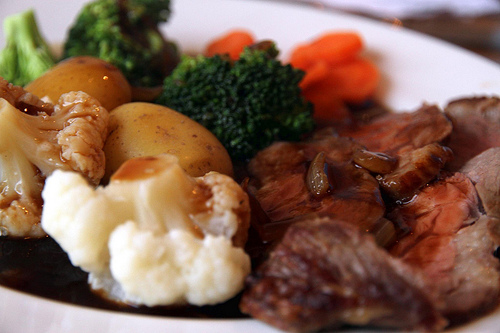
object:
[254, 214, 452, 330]
beef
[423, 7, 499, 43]
table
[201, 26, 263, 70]
carrots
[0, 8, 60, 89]
broccoli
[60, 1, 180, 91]
broccoli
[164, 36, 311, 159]
broccoli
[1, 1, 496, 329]
plate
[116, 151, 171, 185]
mushroom gravy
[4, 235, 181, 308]
sauce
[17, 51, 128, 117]
potato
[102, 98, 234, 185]
potato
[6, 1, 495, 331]
food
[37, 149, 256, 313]
cauliflower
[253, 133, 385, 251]
meat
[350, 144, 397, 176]
mushroom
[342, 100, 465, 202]
steak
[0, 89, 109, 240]
cauliflower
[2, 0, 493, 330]
white plate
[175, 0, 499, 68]
plate`s edge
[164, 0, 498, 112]
white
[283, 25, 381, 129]
carrots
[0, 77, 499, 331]
beef stew